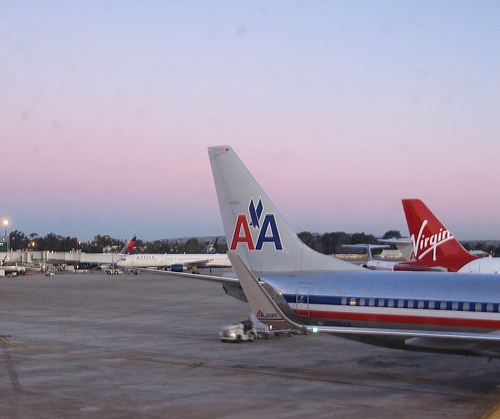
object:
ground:
[1, 271, 498, 418]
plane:
[133, 146, 499, 360]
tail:
[135, 143, 314, 337]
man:
[244, 317, 253, 331]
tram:
[218, 318, 257, 343]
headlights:
[216, 331, 223, 336]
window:
[341, 297, 347, 305]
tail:
[393, 197, 479, 272]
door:
[296, 284, 312, 318]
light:
[312, 327, 318, 333]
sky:
[1, 0, 500, 244]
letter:
[229, 212, 255, 251]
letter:
[255, 213, 284, 251]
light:
[4, 220, 9, 226]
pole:
[3, 227, 7, 252]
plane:
[115, 235, 234, 275]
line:
[0, 334, 25, 349]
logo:
[230, 196, 285, 251]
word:
[410, 220, 455, 261]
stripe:
[282, 294, 499, 315]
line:
[286, 301, 499, 322]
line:
[290, 308, 499, 330]